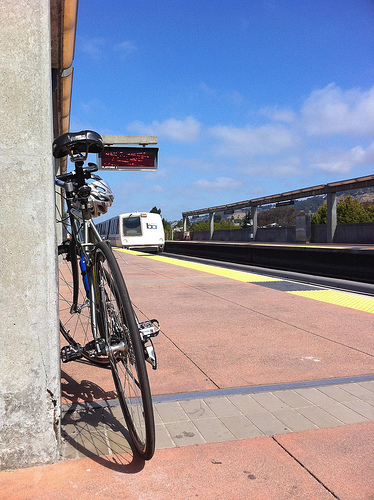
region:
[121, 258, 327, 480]
ground is red and stone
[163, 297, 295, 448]
ground is red and stone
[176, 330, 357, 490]
ground is red and stone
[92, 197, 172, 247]
Public transportation train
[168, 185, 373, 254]
Platform for train station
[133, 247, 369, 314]
Yellow cement platform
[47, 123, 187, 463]
Large blue bicycle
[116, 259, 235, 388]
Red cement platform for train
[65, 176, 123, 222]
Silver safety bike helmet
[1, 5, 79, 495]
Cement wall of a structure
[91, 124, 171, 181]
Train sign displaying information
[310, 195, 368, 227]
Big green trees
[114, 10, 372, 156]
Blue sky with slight clouds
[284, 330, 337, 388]
white stain on ground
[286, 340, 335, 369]
white stain on ground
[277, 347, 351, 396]
white stain on ground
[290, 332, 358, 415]
white stain on ground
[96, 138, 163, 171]
Red lighted sign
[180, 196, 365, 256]
Train platform on opposite side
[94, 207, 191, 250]
White train car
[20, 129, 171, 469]
Blue bicycle with thin tires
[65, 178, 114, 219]
Silver bicycle protective helmet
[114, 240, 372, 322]
Yellow stripe on the edge of the train platform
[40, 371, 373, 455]
Brown tile platform section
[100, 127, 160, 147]
Cement post supporting sign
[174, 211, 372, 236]
Green bushes behind train station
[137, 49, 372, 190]
Blue sky with white clouds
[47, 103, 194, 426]
A bike against a wall.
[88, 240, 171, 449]
The wheel is black.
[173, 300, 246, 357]
The sidewalk is red.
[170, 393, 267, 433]
The sidewalk is brick.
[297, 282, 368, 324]
Yellow line on the ground.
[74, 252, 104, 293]
Blue part of the bike.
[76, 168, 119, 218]
Helmet on the bike.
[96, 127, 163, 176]
Red board hanging high.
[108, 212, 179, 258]
The bus is white.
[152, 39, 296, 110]
The sky is blue.